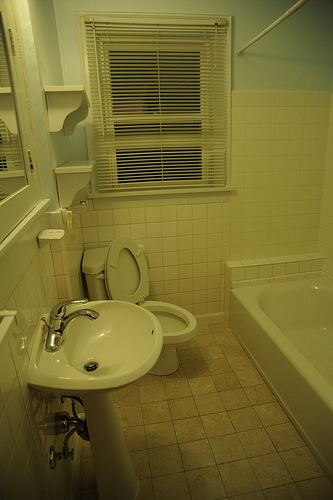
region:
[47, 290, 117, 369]
silver water faucet on the sink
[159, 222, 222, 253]
white tiles on the wall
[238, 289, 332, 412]
large white bath tub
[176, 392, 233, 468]
tan tiles on the floor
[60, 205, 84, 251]
towel holder on the wall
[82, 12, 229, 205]
window with blinds on them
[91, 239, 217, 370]
white porcelain toilet on the ground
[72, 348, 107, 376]
silver drain in the sink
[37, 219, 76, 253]
soap dish on the wall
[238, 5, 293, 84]
shower curtain rod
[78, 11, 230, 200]
a window in the bathroom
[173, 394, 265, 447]
tile flooring in the bathroom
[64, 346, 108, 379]
silver sink drain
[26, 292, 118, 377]
silver sink faucet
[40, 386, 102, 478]
plumbing sticking out of the wall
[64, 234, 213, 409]
a toilet in the corner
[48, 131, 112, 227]
a white shelf in the bathroom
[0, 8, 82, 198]
mirror above the sink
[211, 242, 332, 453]
a white bathtub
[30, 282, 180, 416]
white sink on the wall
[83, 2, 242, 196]
The bathroom has a window in it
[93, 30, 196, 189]
The window has blinds on it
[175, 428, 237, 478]
The tile is brown in color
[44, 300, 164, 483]
The sink is white with silver faucet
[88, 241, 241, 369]
The toilet seat is up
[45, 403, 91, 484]
Pipes are behind the sink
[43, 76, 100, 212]
There are white shelves on the wall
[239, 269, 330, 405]
The bathtub is white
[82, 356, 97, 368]
The sink has a plug in it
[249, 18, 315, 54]
Shower rod over tub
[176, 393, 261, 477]
The floor is made of tile.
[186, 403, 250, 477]
The tile is tan.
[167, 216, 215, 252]
The wall is tile.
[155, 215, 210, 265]
The tile is white.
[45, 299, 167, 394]
The sink is white.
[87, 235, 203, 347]
The toilet is white.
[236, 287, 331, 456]
The tub is white.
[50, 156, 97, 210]
A shelf is on the wall.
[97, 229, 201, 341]
The toilet seat is up.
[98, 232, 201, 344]
The toilet lid is up.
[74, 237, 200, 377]
a corner toilet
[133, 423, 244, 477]
tile flooring in the bathroom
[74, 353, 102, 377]
drain of the sink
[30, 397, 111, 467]
plumbing under the sink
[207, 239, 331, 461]
white large bathtub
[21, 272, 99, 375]
a faucet for the sink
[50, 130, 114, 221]
shelf in the bathroom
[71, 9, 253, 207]
blinds on the window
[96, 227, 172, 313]
toilet seat up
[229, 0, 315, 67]
white thin shower curtain rod